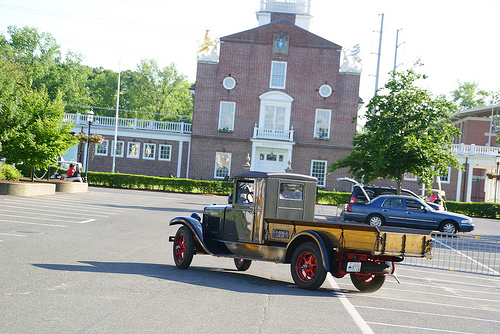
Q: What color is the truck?
A: Yellow.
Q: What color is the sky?
A: White.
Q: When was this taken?
A: Daytime.